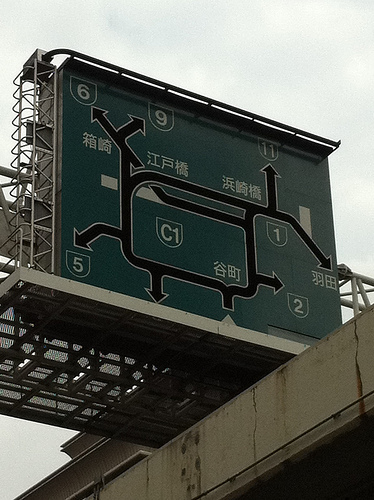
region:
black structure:
[9, 49, 353, 349]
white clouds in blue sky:
[14, 12, 51, 32]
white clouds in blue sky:
[58, 13, 95, 40]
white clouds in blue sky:
[109, 0, 162, 54]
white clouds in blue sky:
[175, 39, 211, 75]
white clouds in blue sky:
[340, 174, 371, 204]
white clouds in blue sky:
[5, 426, 30, 450]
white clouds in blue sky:
[249, 16, 285, 65]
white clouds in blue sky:
[248, 48, 289, 84]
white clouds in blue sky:
[294, 59, 359, 105]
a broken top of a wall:
[107, 317, 370, 498]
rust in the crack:
[349, 326, 366, 418]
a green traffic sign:
[59, 65, 342, 338]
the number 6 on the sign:
[65, 75, 101, 110]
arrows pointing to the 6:
[88, 102, 150, 164]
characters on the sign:
[75, 128, 113, 159]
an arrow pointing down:
[285, 210, 336, 274]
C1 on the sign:
[146, 210, 190, 246]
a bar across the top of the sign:
[43, 42, 351, 159]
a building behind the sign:
[4, 418, 156, 498]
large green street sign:
[19, 88, 335, 318]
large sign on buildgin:
[0, 100, 334, 315]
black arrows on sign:
[75, 106, 186, 189]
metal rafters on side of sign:
[0, 49, 72, 216]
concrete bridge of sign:
[126, 361, 335, 477]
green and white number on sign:
[261, 225, 286, 249]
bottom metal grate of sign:
[24, 326, 126, 408]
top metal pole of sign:
[168, 81, 232, 102]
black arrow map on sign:
[63, 151, 301, 298]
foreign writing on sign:
[205, 252, 249, 284]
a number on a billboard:
[67, 76, 99, 107]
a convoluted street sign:
[63, 75, 340, 334]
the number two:
[286, 291, 311, 317]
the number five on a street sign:
[63, 249, 91, 276]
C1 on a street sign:
[153, 215, 185, 249]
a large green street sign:
[51, 60, 339, 353]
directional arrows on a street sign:
[255, 161, 333, 277]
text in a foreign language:
[78, 131, 113, 158]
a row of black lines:
[71, 108, 174, 299]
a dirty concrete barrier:
[0, 310, 371, 497]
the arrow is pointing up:
[230, 143, 296, 227]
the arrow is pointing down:
[117, 247, 182, 317]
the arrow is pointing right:
[238, 244, 294, 307]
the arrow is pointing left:
[61, 204, 138, 273]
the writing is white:
[74, 129, 270, 212]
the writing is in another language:
[120, 137, 272, 225]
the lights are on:
[8, 346, 145, 397]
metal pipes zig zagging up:
[9, 40, 66, 267]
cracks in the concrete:
[236, 314, 366, 467]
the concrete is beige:
[187, 364, 355, 453]